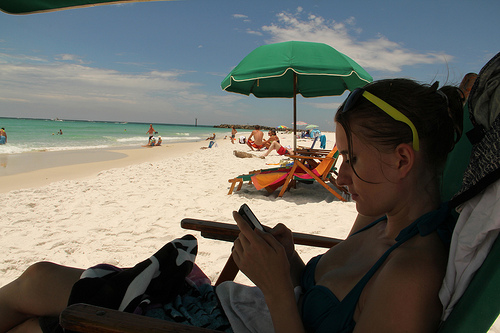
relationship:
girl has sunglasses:
[0, 77, 468, 333] [335, 83, 421, 153]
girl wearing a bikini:
[0, 77, 468, 333] [288, 221, 416, 331]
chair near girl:
[225, 139, 350, 204] [0, 77, 468, 333]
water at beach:
[2, 114, 267, 171] [17, 119, 397, 277]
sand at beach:
[15, 139, 375, 297] [2, 118, 352, 311]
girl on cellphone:
[6, 53, 478, 331] [231, 187, 278, 259]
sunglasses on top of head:
[344, 83, 421, 150] [331, 74, 442, 219]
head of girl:
[331, 74, 442, 219] [0, 77, 468, 333]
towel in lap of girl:
[82, 234, 197, 314] [0, 77, 468, 333]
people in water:
[0, 128, 127, 145] [3, 109, 268, 157]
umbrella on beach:
[212, 28, 397, 122] [4, 113, 400, 331]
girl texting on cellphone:
[0, 77, 468, 333] [236, 202, 261, 234]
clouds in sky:
[1, 47, 226, 124] [4, 5, 498, 133]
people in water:
[52, 121, 132, 138] [4, 114, 247, 204]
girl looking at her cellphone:
[0, 77, 468, 333] [228, 194, 269, 233]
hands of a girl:
[225, 207, 296, 279] [0, 77, 468, 333]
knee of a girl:
[21, 262, 63, 316] [0, 77, 468, 333]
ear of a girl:
[388, 141, 418, 176] [0, 77, 468, 333]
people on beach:
[57, 115, 279, 156] [6, 114, 360, 293]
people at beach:
[143, 125, 316, 160] [6, 114, 360, 293]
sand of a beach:
[0, 130, 360, 297] [7, 96, 348, 268]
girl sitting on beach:
[0, 77, 468, 333] [24, 124, 451, 309]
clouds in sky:
[2, 24, 451, 78] [60, 7, 165, 78]